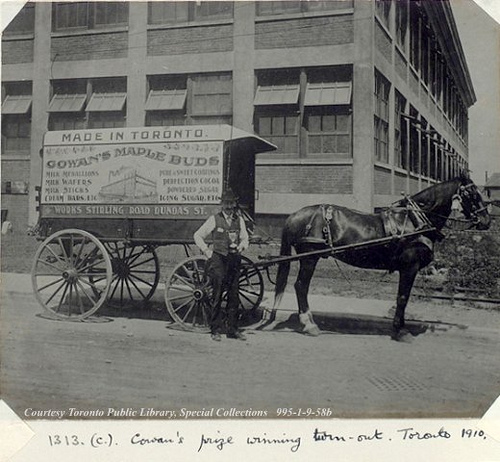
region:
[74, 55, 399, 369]
this is an old photo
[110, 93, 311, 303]
this is black and white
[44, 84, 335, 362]
this is a buggy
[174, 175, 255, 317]
this is a man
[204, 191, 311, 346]
the man is standing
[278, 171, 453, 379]
this is a horse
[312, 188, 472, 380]
the horse is black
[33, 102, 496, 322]
this is a horse drawn cart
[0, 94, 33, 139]
this is a window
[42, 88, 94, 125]
this is a window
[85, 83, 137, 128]
this is a window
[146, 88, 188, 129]
this is a window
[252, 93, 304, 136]
this is a window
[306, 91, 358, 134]
this is a window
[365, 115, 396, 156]
this is a window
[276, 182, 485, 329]
a horse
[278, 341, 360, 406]
the sand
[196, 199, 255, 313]
a man standing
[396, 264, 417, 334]
the horses legs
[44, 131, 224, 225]
a sign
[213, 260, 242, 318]
man is wearing pants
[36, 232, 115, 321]
wheel on the carriage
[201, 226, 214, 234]
a white long sleeve shirt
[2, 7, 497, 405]
a black and white photo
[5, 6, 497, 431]
a scene of old image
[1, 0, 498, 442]
a scene outside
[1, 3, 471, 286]
a building in background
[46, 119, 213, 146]
words MADE IN TORONTO written on the carriage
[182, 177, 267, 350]
a man standing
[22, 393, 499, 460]
words written on the bottom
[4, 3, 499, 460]
a scene during the day time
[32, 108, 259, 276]
this is a cart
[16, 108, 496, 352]
this is a horse drawn cart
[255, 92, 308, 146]
a window in the building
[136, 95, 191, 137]
a window in the building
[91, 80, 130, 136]
a window in the building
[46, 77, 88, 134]
a window in the building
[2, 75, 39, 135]
a window in the building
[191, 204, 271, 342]
a man standing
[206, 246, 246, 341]
a man wearing pants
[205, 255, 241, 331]
pants are black